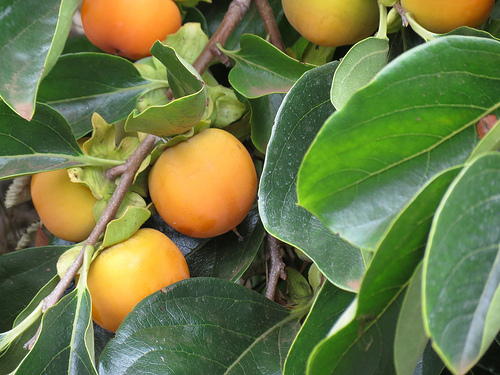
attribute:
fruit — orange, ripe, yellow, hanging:
[30, 171, 113, 243]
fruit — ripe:
[147, 128, 259, 241]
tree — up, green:
[1, 1, 500, 374]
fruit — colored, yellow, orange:
[281, 1, 381, 49]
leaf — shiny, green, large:
[297, 34, 500, 251]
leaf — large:
[423, 150, 499, 374]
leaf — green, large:
[98, 275, 303, 375]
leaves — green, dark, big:
[2, 251, 95, 374]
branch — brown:
[86, 0, 262, 247]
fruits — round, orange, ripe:
[30, 124, 257, 334]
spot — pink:
[475, 112, 497, 139]